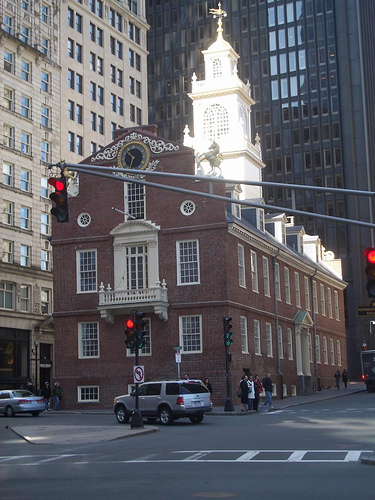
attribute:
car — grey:
[121, 382, 212, 418]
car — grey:
[112, 378, 212, 424]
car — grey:
[0, 387, 46, 417]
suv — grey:
[111, 377, 214, 426]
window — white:
[170, 234, 206, 293]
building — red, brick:
[26, 136, 373, 418]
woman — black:
[239, 373, 250, 413]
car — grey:
[106, 372, 222, 425]